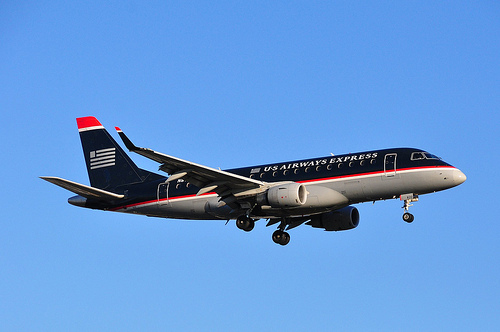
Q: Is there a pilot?
A: No, there are no pilots.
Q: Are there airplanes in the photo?
A: Yes, there is an airplane.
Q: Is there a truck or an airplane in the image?
A: Yes, there is an airplane.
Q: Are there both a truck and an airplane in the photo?
A: No, there is an airplane but no trucks.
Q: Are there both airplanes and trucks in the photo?
A: No, there is an airplane but no trucks.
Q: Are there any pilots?
A: No, there are no pilots.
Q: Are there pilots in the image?
A: No, there are no pilots.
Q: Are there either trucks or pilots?
A: No, there are no pilots or trucks.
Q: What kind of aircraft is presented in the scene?
A: The aircraft is an airplane.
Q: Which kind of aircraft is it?
A: The aircraft is an airplane.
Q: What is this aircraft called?
A: This is an airplane.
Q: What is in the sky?
A: The airplane is in the sky.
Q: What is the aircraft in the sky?
A: The aircraft is an airplane.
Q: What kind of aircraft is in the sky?
A: The aircraft is an airplane.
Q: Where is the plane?
A: The plane is in the sky.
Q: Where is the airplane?
A: The plane is in the sky.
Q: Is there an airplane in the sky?
A: Yes, there is an airplane in the sky.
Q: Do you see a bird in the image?
A: No, there are no birds.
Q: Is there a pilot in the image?
A: No, there are no pilots.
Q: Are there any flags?
A: Yes, there is a flag.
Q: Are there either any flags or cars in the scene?
A: Yes, there is a flag.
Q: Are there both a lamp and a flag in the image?
A: No, there is a flag but no lamps.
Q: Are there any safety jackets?
A: No, there are no safety jackets.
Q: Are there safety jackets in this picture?
A: No, there are no safety jackets.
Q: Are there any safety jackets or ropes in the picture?
A: No, there are no safety jackets or ropes.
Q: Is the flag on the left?
A: Yes, the flag is on the left of the image.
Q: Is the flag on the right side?
A: No, the flag is on the left of the image.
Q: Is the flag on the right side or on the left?
A: The flag is on the left of the image.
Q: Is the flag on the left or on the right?
A: The flag is on the left of the image.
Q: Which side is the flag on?
A: The flag is on the left of the image.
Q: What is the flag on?
A: The flag is on the plane.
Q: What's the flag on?
A: The flag is on the plane.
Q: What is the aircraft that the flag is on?
A: The aircraft is an airplane.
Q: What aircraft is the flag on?
A: The flag is on the airplane.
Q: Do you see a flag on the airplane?
A: Yes, there is a flag on the airplane.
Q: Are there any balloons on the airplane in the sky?
A: No, there is a flag on the airplane.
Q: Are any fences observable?
A: No, there are no fences.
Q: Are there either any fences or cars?
A: No, there are no fences or cars.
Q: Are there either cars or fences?
A: No, there are no fences or cars.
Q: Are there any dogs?
A: No, there are no dogs.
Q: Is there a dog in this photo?
A: No, there are no dogs.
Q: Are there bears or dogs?
A: No, there are no dogs or bears.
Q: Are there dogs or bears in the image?
A: No, there are no dogs or bears.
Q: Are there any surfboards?
A: No, there are no surfboards.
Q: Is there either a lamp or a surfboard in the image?
A: No, there are no surfboards or lamps.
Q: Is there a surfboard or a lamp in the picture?
A: No, there are no surfboards or lamps.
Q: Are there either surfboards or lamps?
A: No, there are no surfboards or lamps.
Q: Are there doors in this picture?
A: Yes, there is a door.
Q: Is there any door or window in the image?
A: Yes, there is a door.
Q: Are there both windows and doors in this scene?
A: Yes, there are both a door and a window.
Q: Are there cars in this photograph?
A: No, there are no cars.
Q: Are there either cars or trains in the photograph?
A: No, there are no cars or trains.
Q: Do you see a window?
A: Yes, there are windows.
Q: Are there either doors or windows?
A: Yes, there are windows.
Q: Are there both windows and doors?
A: Yes, there are both windows and a door.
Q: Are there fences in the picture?
A: No, there are no fences.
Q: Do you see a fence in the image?
A: No, there are no fences.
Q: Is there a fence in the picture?
A: No, there are no fences.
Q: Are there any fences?
A: No, there are no fences.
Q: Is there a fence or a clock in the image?
A: No, there are no fences or clocks.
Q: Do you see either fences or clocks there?
A: No, there are no fences or clocks.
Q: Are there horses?
A: No, there are no horses.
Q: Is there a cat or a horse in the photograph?
A: No, there are no horses or cats.